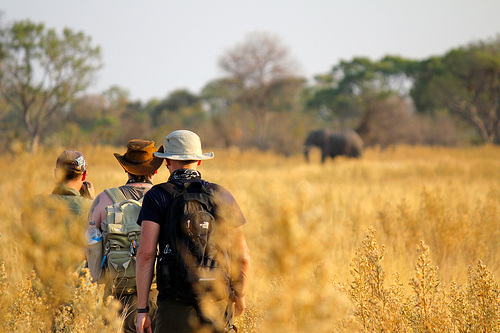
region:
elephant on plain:
[293, 119, 361, 166]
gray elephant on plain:
[293, 116, 355, 184]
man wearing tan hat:
[159, 128, 214, 170]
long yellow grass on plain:
[262, 255, 310, 301]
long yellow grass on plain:
[323, 237, 388, 309]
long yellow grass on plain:
[398, 224, 452, 308]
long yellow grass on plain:
[266, 207, 332, 259]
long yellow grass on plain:
[246, 166, 293, 206]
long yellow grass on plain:
[18, 223, 68, 297]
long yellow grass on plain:
[417, 165, 490, 253]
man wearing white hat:
[145, 123, 256, 325]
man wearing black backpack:
[131, 120, 243, 327]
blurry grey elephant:
[291, 114, 372, 174]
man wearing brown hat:
[80, 133, 187, 305]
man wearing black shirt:
[142, 132, 254, 326]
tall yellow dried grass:
[344, 233, 499, 328]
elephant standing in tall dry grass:
[291, 122, 376, 177]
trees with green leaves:
[362, 46, 497, 123]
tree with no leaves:
[222, 25, 309, 106]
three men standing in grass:
[42, 133, 244, 332]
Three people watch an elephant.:
[55, 125, 265, 330]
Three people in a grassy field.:
[55, 123, 247, 325]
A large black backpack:
[165, 175, 236, 297]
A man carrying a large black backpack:
[135, 130, 253, 331]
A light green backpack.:
[86, 180, 157, 290]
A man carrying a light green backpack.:
[85, 131, 162, 324]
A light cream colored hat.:
[152, 128, 212, 159]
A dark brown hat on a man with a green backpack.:
[111, 137, 162, 177]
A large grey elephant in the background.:
[300, 125, 365, 165]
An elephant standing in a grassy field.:
[298, 126, 363, 161]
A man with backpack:
[146, 130, 253, 332]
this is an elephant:
[301, 125, 368, 158]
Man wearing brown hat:
[115, 139, 165, 179]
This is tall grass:
[272, 180, 499, 319]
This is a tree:
[216, 28, 297, 78]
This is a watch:
[133, 303, 152, 318]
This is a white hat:
[156, 129, 215, 163]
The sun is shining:
[95, 3, 212, 49]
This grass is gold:
[270, 175, 478, 285]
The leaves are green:
[421, 45, 493, 111]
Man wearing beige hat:
[127, 128, 248, 332]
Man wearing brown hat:
[84, 137, 171, 332]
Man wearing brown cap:
[32, 146, 97, 282]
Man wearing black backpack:
[127, 127, 245, 330]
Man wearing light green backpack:
[84, 133, 163, 331]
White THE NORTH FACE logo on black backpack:
[192, 216, 209, 232]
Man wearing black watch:
[127, 127, 248, 332]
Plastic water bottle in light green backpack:
[84, 215, 101, 243]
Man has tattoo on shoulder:
[78, 133, 165, 330]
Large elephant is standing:
[293, 122, 366, 169]